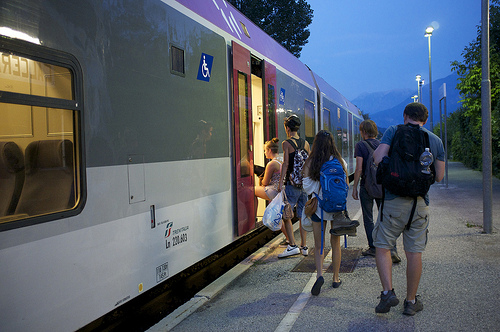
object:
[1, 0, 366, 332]
train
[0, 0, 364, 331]
car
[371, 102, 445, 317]
man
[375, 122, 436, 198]
backpack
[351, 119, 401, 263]
man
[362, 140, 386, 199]
backpack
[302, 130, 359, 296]
girl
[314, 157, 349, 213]
backpack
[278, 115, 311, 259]
man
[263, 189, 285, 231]
bag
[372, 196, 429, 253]
pants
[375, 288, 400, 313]
shoe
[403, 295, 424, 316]
shoe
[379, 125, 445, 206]
shirt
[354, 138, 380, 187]
shirt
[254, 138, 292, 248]
woman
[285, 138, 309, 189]
backpack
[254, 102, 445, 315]
passengers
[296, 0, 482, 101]
sky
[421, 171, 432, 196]
pocket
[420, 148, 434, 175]
water bottle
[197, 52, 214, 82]
sign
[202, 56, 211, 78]
wheelchair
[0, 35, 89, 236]
window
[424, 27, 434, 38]
light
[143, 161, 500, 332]
boarding area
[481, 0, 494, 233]
pole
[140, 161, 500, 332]
sidewalk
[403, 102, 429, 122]
hair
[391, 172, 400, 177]
red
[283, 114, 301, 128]
cap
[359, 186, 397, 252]
jeans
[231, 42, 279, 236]
doors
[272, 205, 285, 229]
writing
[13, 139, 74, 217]
seat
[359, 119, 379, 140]
head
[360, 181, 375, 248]
leg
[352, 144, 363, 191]
arm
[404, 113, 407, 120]
ear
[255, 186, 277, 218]
leg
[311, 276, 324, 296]
shoe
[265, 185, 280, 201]
shorts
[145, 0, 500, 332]
station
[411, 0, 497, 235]
streetlights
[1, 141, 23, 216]
seat